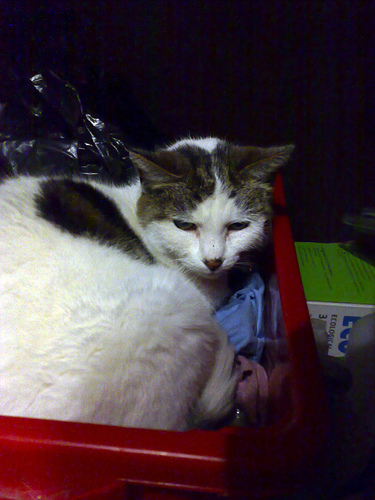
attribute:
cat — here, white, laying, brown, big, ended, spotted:
[0, 134, 297, 439]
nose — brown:
[205, 254, 222, 271]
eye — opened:
[174, 214, 204, 239]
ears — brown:
[118, 142, 302, 181]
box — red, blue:
[3, 126, 328, 498]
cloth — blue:
[210, 270, 282, 361]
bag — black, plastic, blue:
[1, 50, 137, 179]